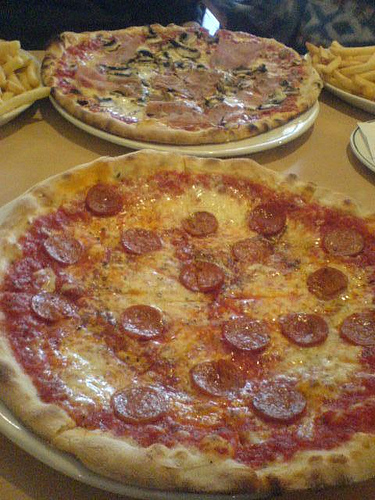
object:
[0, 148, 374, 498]
pizza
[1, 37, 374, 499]
table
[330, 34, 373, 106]
french fries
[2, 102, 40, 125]
plate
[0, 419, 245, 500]
plate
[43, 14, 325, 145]
pizza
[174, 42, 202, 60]
mushrooms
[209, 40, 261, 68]
ham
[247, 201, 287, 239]
pepperoni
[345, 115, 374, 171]
plate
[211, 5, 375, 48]
shirt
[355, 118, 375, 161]
napkin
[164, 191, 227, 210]
cheese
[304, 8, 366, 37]
pattern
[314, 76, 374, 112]
plate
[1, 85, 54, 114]
fry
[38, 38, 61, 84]
crust